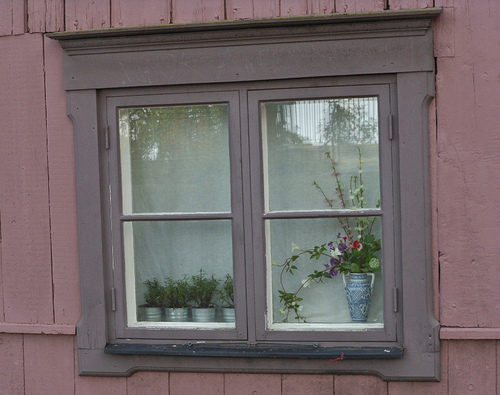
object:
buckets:
[137, 304, 162, 322]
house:
[0, 1, 498, 394]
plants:
[188, 268, 220, 323]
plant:
[270, 144, 382, 324]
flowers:
[354, 168, 364, 177]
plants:
[217, 270, 237, 323]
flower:
[328, 160, 337, 168]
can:
[163, 306, 188, 322]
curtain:
[127, 97, 382, 324]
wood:
[0, 0, 499, 394]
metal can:
[220, 304, 235, 325]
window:
[44, 6, 443, 383]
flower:
[365, 257, 381, 270]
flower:
[278, 306, 288, 319]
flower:
[300, 276, 313, 289]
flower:
[289, 241, 301, 253]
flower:
[291, 303, 303, 313]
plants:
[161, 275, 192, 322]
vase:
[341, 270, 374, 322]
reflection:
[265, 97, 378, 174]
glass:
[115, 94, 383, 324]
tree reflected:
[117, 102, 230, 163]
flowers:
[355, 184, 364, 194]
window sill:
[103, 337, 405, 359]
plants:
[136, 277, 165, 321]